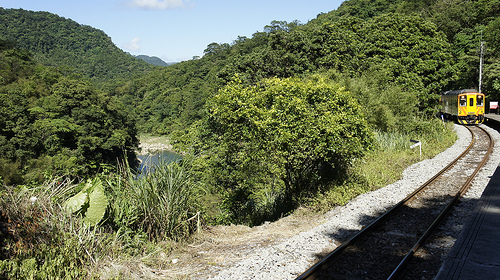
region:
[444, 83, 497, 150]
a trian on the tracks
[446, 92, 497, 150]
a yellow train on track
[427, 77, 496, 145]
a passenger train on track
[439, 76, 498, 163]
a yellow passenger train on track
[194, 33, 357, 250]
trees with green leaves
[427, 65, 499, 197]
a track with train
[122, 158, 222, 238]
fluffy green bush along the track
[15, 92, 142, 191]
fluffy green bush along the track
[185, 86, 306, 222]
fluffy green bush along the track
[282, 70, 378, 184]
fluffy green bush along the track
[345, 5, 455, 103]
fluffy green tree along the track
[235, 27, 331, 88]
fluffy green bush along the track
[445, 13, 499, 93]
fluffy green bush along the track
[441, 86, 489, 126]
yellow train along the rusty track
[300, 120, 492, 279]
rusty track along the river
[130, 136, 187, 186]
river along the rusty track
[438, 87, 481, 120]
black and yellow train car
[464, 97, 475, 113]
back door on the train car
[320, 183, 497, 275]
shadow tree on train tracks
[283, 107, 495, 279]
gravel around the train tracks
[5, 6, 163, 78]
tree covered mountain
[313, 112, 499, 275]
tracks the train is traveling on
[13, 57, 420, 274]
bushes beside the train tracks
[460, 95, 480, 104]
windows on the back of the train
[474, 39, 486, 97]
utility pole next to the train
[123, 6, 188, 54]
wispy clouds in the sky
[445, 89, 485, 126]
yellow passenger train car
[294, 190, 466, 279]
rusty steel railroad tracks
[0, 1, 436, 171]
trees lining the railroad tracks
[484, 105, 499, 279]
the train station platform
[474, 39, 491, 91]
a wooden communication pole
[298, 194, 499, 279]
a shadow of a tree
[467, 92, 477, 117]
the yellow rear door of a passenger train car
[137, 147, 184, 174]
a small pond in a gully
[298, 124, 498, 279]
gravel along the train tracks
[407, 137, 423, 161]
a train traffic marker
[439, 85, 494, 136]
face of the train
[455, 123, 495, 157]
track under the train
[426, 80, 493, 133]
yellow train in photo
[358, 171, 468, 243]
shadow on the track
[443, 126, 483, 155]
rocks on the ground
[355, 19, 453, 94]
leaves on the tree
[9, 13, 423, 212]
many trees next to train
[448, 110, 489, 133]
bottom of the train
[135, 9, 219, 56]
sky above the land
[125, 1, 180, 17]
cloud in the sky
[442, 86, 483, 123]
Yellow train car on a track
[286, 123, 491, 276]
Rusted train tracks in the country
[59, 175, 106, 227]
Wide green leaf in bushes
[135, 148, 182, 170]
Part of lake between bushes